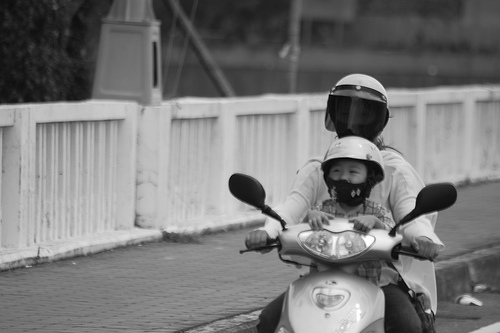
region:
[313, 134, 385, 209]
child wearing a helmet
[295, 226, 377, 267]
headlight on a scooter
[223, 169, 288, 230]
right mirror of a scooter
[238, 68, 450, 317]
mother and son riding a scooter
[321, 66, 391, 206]
mother and son wearing helmets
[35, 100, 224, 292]
bridge railing and sidewalk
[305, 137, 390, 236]
boy with hands on scooter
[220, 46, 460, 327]
scooter going across a bridge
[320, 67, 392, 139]
woman wearing full faced helmet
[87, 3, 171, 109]
street lamp base on bridge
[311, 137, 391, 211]
The boy is wearing a helmet.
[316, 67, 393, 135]
The person is wearing a helmet.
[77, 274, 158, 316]
The pavement is dark in color.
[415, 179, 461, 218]
The left rear view mirror is black.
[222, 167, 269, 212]
The right rear view mirror is black.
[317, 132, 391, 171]
The boys helmet is white.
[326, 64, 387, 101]
The persons helmet is white.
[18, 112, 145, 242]
The fence is white in color.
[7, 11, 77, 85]
The tree in the background is blurry.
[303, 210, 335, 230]
The boys right hand has five fingers.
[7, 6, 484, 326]
Classic black and white photo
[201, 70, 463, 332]
A child with the parent on the scooter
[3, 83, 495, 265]
White railing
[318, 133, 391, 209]
A child wearing a helmet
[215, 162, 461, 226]
Two rear view mirrors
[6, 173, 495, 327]
Sidewalk with white railing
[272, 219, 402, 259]
Headlight of the scooter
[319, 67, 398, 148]
Full face helmet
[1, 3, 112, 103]
Blurry image of trees in the background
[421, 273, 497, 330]
Road with markings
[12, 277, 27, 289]
a brick on sidewalk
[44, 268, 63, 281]
a brick on sidewalk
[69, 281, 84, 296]
a brick on sidewalk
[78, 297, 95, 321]
a brick on sidewalk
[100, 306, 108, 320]
a brick on sidewalk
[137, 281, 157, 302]
a brick on sidewalk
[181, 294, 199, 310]
a brick on sidewalk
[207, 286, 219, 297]
a brick on sidewalk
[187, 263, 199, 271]
a brick on sidewalk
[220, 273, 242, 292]
a brick on sidewalk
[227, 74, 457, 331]
Two people riding a scooter.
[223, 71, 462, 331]
A woman and a child on a scooter.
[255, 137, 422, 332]
A child wearing a helmet.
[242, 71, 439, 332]
A woman wearing a helmet.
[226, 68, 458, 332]
A woman and a child wearing helmets.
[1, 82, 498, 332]
A bridge with a barrier.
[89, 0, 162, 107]
A metal pole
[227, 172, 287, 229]
Side mirror.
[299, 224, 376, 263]
Two headlights.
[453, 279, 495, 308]
Trash on the ground.